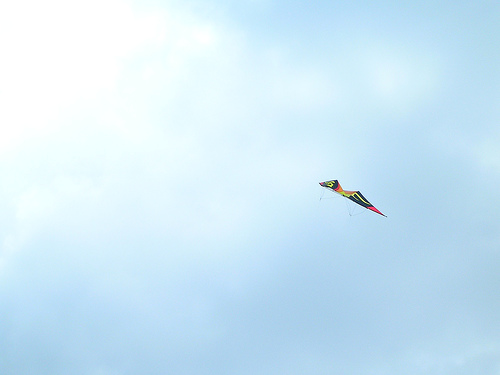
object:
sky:
[464, 84, 498, 131]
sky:
[456, 318, 497, 356]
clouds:
[7, 120, 63, 179]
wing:
[347, 186, 390, 221]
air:
[9, 33, 55, 159]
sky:
[5, 349, 60, 371]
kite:
[314, 162, 391, 224]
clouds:
[133, 2, 157, 34]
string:
[316, 191, 327, 202]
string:
[345, 208, 356, 218]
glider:
[308, 174, 391, 223]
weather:
[3, 2, 482, 357]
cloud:
[351, 40, 444, 106]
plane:
[314, 175, 395, 221]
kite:
[303, 165, 387, 224]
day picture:
[5, 2, 499, 364]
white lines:
[346, 197, 365, 207]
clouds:
[3, 67, 37, 120]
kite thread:
[315, 177, 386, 219]